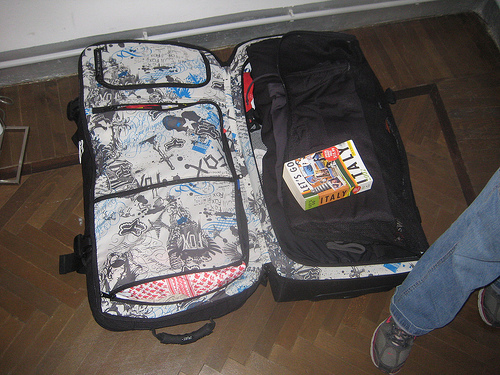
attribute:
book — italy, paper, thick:
[271, 137, 377, 213]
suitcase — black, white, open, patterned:
[64, 26, 440, 346]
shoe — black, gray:
[368, 302, 417, 372]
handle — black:
[156, 316, 220, 347]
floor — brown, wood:
[2, 10, 500, 374]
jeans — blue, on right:
[382, 162, 499, 339]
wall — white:
[1, 1, 482, 86]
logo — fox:
[185, 148, 228, 183]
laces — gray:
[388, 324, 411, 349]